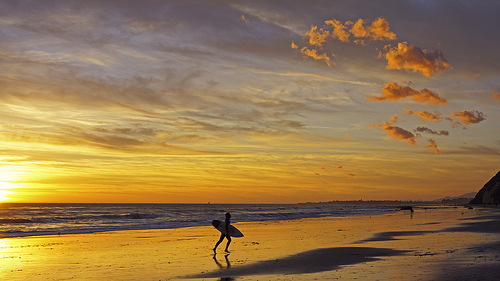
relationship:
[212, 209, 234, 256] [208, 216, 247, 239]
person holding surf board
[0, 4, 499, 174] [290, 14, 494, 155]
sky has clouds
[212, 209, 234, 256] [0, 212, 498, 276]
person walking on beach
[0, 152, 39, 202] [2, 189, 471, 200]
sun going down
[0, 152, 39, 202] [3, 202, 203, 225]
sunset over ocean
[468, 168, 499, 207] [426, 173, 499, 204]
hill in distance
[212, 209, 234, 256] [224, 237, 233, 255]
person seen a leg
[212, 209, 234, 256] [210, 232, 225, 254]
person seen a leg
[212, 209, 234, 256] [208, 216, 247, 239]
person carrying surfboard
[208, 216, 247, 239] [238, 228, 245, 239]
surf board has pointy edge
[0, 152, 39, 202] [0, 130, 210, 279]
sund has light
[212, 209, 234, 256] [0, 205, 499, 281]
person on beach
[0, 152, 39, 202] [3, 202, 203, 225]
sun setting into ocean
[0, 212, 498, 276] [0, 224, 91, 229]
beach has wave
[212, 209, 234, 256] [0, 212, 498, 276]
person on beach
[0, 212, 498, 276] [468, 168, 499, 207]
beach has a hill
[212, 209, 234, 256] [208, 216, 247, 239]
person with surf board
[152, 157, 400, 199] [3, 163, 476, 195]
cloud on horizon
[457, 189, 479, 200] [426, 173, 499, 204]
hill in distance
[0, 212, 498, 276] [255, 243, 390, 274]
beach area shadowed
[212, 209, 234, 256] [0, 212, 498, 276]
person running on beach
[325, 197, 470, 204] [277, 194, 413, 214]
trees in row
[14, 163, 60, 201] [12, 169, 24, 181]
corona seen section